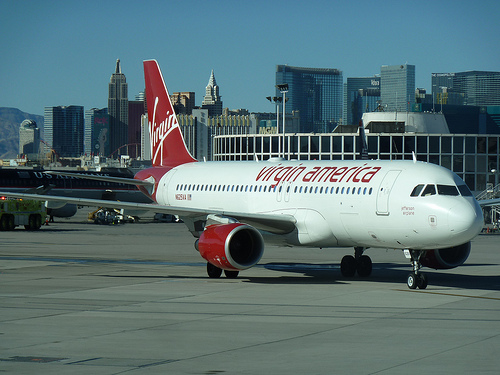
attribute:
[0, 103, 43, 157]
mountain — distant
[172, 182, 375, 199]
windows — tiny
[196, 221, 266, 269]
engine — red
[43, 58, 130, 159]
buildings — some , distance 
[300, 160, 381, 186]
word — america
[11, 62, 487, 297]
airport vehicle — large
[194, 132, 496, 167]
walls — glass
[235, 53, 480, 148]
sky line — city sky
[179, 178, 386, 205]
windows — passengers 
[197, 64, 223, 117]
building — tall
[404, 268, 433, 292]
wheel — small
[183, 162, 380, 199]
windows — long row 